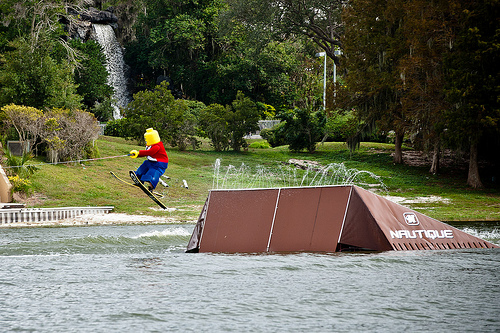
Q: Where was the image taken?
A: It was taken at the shore.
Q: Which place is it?
A: It is a shore.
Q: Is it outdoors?
A: Yes, it is outdoors.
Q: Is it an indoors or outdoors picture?
A: It is outdoors.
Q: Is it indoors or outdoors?
A: It is outdoors.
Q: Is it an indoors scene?
A: No, it is outdoors.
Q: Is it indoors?
A: No, it is outdoors.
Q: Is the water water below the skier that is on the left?
A: Yes, the water is below the skier.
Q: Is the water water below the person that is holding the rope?
A: Yes, the water is below the skier.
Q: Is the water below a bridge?
A: No, the water is below the skier.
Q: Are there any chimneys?
A: No, there are no chimneys.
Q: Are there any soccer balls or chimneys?
A: No, there are no chimneys or soccer balls.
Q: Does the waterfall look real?
A: Yes, the waterfall is real.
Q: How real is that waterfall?
A: The waterfall is real.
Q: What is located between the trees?
A: The waterfall is between the trees.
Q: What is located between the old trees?
A: The waterfall is between the trees.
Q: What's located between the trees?
A: The waterfall is between the trees.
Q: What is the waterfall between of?
A: The waterfall is between the trees.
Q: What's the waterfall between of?
A: The waterfall is between the trees.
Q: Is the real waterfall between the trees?
A: Yes, the waterfall is between the trees.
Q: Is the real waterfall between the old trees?
A: Yes, the waterfall is between the trees.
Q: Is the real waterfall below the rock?
A: Yes, the waterfall is below the rock.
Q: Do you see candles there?
A: No, there are no candles.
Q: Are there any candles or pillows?
A: No, there are no candles or pillows.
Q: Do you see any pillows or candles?
A: No, there are no candles or pillows.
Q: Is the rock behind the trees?
A: Yes, the rock is behind the trees.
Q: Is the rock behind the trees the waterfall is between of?
A: Yes, the rock is behind the trees.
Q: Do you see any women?
A: No, there are no women.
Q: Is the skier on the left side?
A: Yes, the skier is on the left of the image.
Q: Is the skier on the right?
A: No, the skier is on the left of the image.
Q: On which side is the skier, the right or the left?
A: The skier is on the left of the image.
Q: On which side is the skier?
A: The skier is on the left of the image.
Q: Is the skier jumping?
A: Yes, the skier is jumping.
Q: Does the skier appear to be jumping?
A: Yes, the skier is jumping.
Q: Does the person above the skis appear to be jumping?
A: Yes, the skier is jumping.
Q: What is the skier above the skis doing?
A: The skier is jumping.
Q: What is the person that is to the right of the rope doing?
A: The skier is jumping.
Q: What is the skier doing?
A: The skier is jumping.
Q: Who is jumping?
A: The skier is jumping.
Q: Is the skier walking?
A: No, the skier is jumping.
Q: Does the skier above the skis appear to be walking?
A: No, the skier is jumping.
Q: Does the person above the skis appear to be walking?
A: No, the skier is jumping.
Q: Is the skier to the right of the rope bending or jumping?
A: The skier is jumping.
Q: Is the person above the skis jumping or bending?
A: The skier is jumping.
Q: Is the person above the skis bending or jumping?
A: The skier is jumping.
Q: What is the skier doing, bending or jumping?
A: The skier is jumping.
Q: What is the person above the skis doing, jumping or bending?
A: The skier is jumping.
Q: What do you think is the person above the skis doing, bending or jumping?
A: The skier is jumping.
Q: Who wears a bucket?
A: The skier wears a bucket.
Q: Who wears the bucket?
A: The skier wears a bucket.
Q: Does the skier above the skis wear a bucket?
A: Yes, the skier wears a bucket.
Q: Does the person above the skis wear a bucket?
A: Yes, the skier wears a bucket.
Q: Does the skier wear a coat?
A: No, the skier wears a bucket.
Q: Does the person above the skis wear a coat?
A: No, the skier wears a bucket.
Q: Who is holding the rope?
A: The skier is holding the rope.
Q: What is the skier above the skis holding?
A: The skier is holding the rope.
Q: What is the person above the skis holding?
A: The skier is holding the rope.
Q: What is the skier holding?
A: The skier is holding the rope.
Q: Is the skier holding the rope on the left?
A: Yes, the skier is holding the rope.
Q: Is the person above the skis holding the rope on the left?
A: Yes, the skier is holding the rope.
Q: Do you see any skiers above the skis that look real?
A: Yes, there is a skier above the skis.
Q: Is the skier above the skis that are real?
A: Yes, the skier is above the skis.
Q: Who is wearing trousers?
A: The skier is wearing trousers.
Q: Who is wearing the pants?
A: The skier is wearing trousers.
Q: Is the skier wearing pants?
A: Yes, the skier is wearing pants.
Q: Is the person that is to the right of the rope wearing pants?
A: Yes, the skier is wearing pants.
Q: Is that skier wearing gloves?
A: No, the skier is wearing pants.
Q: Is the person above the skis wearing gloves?
A: No, the skier is wearing pants.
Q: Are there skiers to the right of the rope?
A: Yes, there is a skier to the right of the rope.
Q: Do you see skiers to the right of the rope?
A: Yes, there is a skier to the right of the rope.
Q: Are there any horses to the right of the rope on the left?
A: No, there is a skier to the right of the rope.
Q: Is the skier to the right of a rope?
A: Yes, the skier is to the right of a rope.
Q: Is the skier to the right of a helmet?
A: No, the skier is to the right of a rope.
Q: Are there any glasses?
A: No, there are no glasses.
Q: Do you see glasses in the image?
A: No, there are no glasses.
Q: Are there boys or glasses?
A: No, there are no glasses or boys.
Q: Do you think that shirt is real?
A: Yes, the shirt is real.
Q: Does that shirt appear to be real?
A: Yes, the shirt is real.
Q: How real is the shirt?
A: The shirt is real.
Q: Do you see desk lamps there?
A: No, there are no desk lamps.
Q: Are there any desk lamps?
A: No, there are no desk lamps.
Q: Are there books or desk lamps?
A: No, there are no desk lamps or books.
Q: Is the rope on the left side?
A: Yes, the rope is on the left of the image.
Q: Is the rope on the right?
A: No, the rope is on the left of the image.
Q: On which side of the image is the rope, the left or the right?
A: The rope is on the left of the image.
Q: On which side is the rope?
A: The rope is on the left of the image.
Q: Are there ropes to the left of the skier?
A: Yes, there is a rope to the left of the skier.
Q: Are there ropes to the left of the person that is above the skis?
A: Yes, there is a rope to the left of the skier.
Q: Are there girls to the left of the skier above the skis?
A: No, there is a rope to the left of the skier.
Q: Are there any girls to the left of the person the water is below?
A: No, there is a rope to the left of the skier.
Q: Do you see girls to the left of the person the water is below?
A: No, there is a rope to the left of the skier.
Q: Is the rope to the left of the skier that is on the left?
A: Yes, the rope is to the left of the skier.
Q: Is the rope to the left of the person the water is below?
A: Yes, the rope is to the left of the skier.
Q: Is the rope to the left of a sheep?
A: No, the rope is to the left of the skier.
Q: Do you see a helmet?
A: No, there are no helmets.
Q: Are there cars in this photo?
A: No, there are no cars.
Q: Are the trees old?
A: Yes, the trees are old.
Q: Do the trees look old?
A: Yes, the trees are old.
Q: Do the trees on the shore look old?
A: Yes, the trees are old.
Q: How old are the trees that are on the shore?
A: The trees are old.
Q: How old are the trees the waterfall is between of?
A: The trees are old.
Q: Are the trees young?
A: No, the trees are old.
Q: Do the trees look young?
A: No, the trees are old.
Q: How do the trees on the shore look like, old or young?
A: The trees are old.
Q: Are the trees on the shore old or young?
A: The trees are old.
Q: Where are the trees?
A: The trees are on the shore.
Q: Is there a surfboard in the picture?
A: No, there are no surfboards.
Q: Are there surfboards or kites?
A: No, there are no surfboards or kites.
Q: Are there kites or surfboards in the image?
A: No, there are no surfboards or kites.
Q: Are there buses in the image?
A: No, there are no buses.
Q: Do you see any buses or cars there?
A: No, there are no buses or cars.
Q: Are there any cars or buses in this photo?
A: No, there are no buses or cars.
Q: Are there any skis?
A: Yes, there are skis.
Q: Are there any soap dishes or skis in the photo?
A: Yes, there are skis.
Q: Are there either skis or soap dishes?
A: Yes, there are skis.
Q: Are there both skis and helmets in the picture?
A: No, there are skis but no helmets.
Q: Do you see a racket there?
A: No, there are no rackets.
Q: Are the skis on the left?
A: Yes, the skis are on the left of the image.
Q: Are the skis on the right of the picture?
A: No, the skis are on the left of the image.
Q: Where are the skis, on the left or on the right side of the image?
A: The skis are on the left of the image.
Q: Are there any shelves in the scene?
A: No, there are no shelves.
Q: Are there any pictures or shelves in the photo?
A: No, there are no shelves or pictures.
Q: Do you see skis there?
A: Yes, there are skis.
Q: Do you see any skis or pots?
A: Yes, there are skis.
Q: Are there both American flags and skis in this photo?
A: No, there are skis but no American flags.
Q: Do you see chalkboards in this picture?
A: No, there are no chalkboards.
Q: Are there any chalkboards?
A: No, there are no chalkboards.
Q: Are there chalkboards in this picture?
A: No, there are no chalkboards.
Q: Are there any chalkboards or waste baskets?
A: No, there are no chalkboards or waste baskets.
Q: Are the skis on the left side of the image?
A: Yes, the skis are on the left of the image.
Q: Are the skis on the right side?
A: No, the skis are on the left of the image.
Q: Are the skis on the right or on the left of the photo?
A: The skis are on the left of the image.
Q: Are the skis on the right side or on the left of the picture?
A: The skis are on the left of the image.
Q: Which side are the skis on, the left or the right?
A: The skis are on the left of the image.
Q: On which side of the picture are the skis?
A: The skis are on the left of the image.